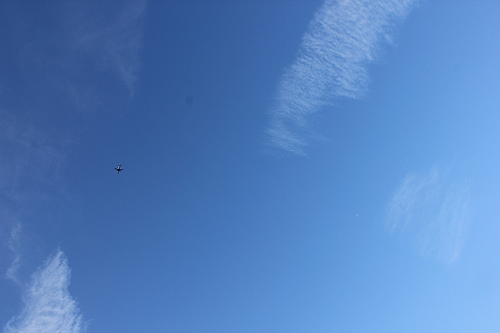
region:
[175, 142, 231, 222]
part of the sky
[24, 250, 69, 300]
part of a cloud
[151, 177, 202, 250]
part of the sky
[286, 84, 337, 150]
part of a cloud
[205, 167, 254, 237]
part of the sky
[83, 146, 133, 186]
part of a plane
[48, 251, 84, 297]
edge of a cloud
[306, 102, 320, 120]
part of a cloud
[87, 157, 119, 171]
part of a plane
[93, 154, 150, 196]
aircraft flying high in sky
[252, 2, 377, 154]
white cloud in blue sky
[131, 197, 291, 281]
clear blue cloudless sky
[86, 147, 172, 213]
aircraft flying in a clear blue sky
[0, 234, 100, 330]
thin white cloud in sky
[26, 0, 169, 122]
barely visible white cloud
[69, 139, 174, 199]
large jet aircraft in sky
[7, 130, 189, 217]
aircraft flying in a blue sky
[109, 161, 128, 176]
jet aircraft flying very high in sky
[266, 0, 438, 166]
large white cloud in bright blue sky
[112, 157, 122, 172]
A plane in the sky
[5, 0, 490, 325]
A clear blue sky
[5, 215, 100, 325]
A cloud in the sky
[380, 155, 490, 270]
A cloud in the sky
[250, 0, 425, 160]
A cloud in the sky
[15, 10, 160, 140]
A cloud in the sky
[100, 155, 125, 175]
an airplane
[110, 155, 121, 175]
A plane flying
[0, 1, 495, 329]
A clear sky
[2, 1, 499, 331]
A blue sky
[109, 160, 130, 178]
plane flying through the sky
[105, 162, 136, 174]
black plane flying overhead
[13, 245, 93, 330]
white cloud in left corner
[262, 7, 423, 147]
long cloud in upper corner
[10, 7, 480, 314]
sky plane if flying through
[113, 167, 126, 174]
wings of black plane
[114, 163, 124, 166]
tail wing of black plane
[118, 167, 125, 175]
nose of black plane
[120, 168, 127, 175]
right wing of black plane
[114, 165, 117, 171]
left wing of black plane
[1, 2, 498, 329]
a color picture of the sky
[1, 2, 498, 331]
a blue sky with dim white clouds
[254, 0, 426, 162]
a diffuse white cloud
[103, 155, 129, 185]
an aircraft flying in a blue sky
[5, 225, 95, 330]
a diffuse cloud on left side of the picture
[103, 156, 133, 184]
the aircraft is flying forward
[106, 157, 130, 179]
the aircraft has two wings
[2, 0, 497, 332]
the sky has different tones of blue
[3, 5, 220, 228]
aircraft is flying in the dark blue part of the sky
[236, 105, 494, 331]
part of the sky that is light blue